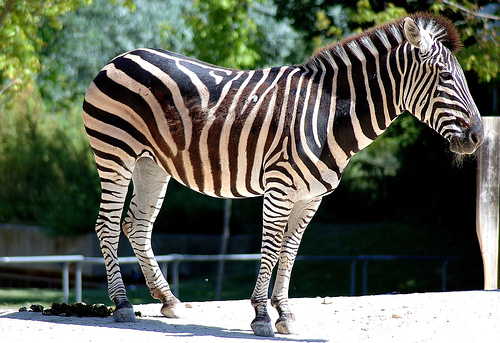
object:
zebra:
[79, 10, 488, 338]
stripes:
[202, 79, 241, 192]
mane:
[305, 17, 447, 72]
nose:
[468, 126, 486, 147]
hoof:
[274, 316, 297, 335]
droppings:
[41, 301, 112, 318]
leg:
[248, 170, 297, 304]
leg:
[268, 197, 327, 302]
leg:
[92, 147, 135, 297]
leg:
[121, 161, 167, 289]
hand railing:
[0, 250, 396, 268]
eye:
[437, 71, 454, 83]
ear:
[400, 16, 422, 51]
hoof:
[250, 315, 274, 338]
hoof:
[111, 305, 138, 323]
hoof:
[158, 300, 191, 320]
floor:
[0, 289, 497, 343]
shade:
[185, 281, 209, 298]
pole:
[473, 115, 499, 292]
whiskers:
[455, 154, 468, 167]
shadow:
[0, 306, 333, 342]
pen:
[0, 251, 482, 307]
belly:
[146, 103, 275, 199]